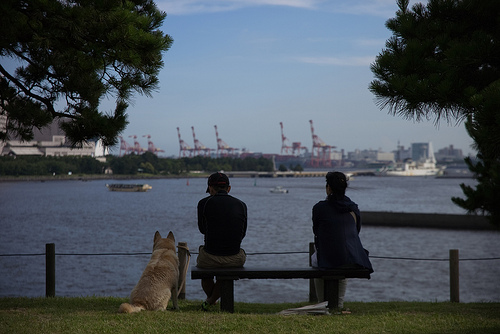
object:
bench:
[190, 266, 371, 312]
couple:
[197, 172, 373, 314]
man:
[197, 173, 246, 311]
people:
[310, 171, 370, 315]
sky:
[0, 0, 479, 158]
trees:
[368, 0, 500, 216]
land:
[360, 210, 499, 232]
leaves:
[18, 20, 19, 27]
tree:
[0, 0, 173, 149]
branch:
[0, 62, 128, 149]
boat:
[379, 160, 440, 176]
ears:
[153, 230, 161, 241]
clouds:
[271, 53, 380, 67]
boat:
[438, 166, 479, 177]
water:
[0, 176, 499, 302]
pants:
[197, 248, 249, 311]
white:
[96, 146, 103, 156]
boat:
[269, 187, 289, 194]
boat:
[107, 183, 153, 192]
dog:
[119, 230, 176, 312]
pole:
[449, 248, 461, 303]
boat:
[361, 211, 497, 230]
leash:
[176, 245, 191, 294]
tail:
[117, 301, 146, 312]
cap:
[205, 172, 231, 193]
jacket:
[310, 197, 374, 279]